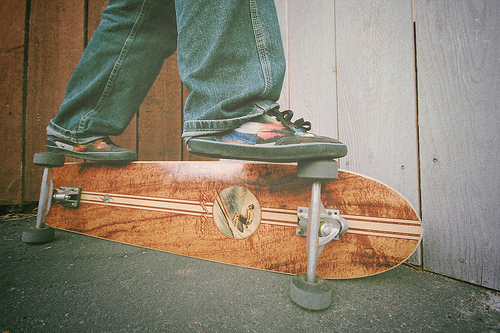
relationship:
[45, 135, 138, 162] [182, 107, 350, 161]
shoe behind shoe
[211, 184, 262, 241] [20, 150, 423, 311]
circle on board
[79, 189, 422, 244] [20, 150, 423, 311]
stripe on board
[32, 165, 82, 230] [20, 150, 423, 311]
truck on board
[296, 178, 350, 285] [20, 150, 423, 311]
truck on board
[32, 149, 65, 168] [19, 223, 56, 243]
wheel below wheel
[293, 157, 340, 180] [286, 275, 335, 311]
wheel below wheel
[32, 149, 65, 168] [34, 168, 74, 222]
wheel attached to truck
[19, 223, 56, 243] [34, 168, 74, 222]
wheel attached to truck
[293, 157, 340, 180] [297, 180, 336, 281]
wheel attached to truck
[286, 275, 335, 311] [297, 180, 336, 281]
wheel attached to truck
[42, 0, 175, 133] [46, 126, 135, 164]
pant leg above shoe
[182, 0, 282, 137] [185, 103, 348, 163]
pant leg above shoe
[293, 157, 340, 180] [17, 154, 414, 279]
wheel on skateboard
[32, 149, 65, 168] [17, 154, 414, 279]
wheel on skateboard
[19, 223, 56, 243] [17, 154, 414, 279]
wheel on skateboard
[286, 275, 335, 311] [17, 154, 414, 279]
wheel on skateboard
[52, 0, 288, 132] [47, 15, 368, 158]
jeans on skateboarder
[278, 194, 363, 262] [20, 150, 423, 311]
axle on board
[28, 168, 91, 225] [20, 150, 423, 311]
axle on board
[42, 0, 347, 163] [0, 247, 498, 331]
man on pavement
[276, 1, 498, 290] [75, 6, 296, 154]
wall behind skateboarder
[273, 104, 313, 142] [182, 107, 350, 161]
shoelace in shoe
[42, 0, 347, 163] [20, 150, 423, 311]
man on board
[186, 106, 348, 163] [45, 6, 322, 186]
shoe on person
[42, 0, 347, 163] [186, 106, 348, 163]
man wearing shoe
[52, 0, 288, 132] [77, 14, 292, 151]
jeans wearing person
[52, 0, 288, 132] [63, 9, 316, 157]
jeans on person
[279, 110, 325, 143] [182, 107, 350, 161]
lace on shoe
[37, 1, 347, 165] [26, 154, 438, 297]
person on board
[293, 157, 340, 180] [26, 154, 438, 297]
wheel on board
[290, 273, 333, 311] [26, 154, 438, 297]
wheel on board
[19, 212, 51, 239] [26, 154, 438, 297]
wheel on board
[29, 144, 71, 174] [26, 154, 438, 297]
wheel on board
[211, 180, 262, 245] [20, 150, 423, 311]
surf picture on board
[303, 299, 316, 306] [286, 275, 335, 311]
part of a wheel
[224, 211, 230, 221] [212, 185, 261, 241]
part of a circle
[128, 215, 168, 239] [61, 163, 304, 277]
part of a board